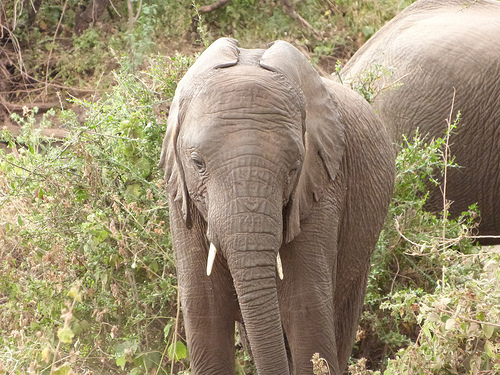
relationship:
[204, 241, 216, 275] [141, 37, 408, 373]
tusk part of elephant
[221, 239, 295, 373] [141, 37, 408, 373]
trunk part of elephant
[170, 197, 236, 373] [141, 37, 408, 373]
leg part of elephant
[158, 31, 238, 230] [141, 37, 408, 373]
ear part of elephant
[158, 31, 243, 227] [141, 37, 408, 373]
ear part of elephant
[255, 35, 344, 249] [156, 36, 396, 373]
ear part of elephant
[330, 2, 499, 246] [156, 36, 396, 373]
elephant behind elephant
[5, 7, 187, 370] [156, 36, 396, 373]
grass behind elephant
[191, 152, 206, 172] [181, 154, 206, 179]
eye part of elephant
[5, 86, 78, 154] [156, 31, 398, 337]
branch behind elephant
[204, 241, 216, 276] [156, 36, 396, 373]
tusk part of elephant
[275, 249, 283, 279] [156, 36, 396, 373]
tusk part of elephant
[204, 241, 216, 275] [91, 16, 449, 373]
tusk part of elephant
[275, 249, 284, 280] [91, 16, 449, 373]
tusk part of elephant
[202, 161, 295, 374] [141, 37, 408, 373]
trunk on elephant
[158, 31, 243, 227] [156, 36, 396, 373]
ear on elephant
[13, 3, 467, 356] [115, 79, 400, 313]
area near elephant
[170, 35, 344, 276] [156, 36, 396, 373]
head of elephant